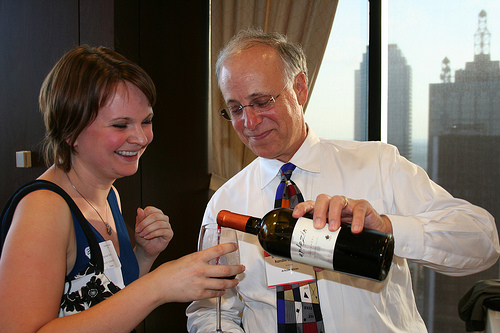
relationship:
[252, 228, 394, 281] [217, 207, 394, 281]
wine inside bottle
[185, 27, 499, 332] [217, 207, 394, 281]
man holding bottle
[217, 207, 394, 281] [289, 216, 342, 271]
bottle has label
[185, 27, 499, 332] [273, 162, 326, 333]
man wearing tie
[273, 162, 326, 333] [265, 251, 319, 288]
tie has nametag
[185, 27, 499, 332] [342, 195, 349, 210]
man wearing ring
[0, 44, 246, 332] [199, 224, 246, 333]
woman holding wineglass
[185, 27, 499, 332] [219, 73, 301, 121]
man wearing eyeglasses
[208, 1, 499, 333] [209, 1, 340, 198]
window has curtain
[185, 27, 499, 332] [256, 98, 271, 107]
man has eye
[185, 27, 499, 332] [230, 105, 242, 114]
man has eye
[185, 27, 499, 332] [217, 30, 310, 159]
man has head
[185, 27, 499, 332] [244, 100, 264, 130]
man has nose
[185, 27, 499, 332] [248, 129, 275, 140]
man has mouth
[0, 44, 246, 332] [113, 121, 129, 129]
woman has eye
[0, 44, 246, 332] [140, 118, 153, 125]
woman has eye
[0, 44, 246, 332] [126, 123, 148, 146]
woman has nose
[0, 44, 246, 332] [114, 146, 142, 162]
woman has mouth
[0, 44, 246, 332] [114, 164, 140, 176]
woman has chin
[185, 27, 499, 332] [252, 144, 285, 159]
man has chin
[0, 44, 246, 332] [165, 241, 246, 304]
woman has hand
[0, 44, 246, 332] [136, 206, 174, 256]
woman has hand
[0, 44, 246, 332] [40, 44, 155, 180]
woman has head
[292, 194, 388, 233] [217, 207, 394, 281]
hand holds bottle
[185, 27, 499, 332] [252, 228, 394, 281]
man pouring wine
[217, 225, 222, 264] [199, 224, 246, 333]
wine inside wineglass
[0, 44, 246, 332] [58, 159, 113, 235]
woman wearing necklace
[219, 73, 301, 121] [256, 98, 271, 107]
eyeglasses are in front of eye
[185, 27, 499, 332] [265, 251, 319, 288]
man wearing nametag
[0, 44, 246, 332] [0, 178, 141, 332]
woman wearing dress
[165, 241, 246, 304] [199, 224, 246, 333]
hand holding wineglass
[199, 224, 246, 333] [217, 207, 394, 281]
wineglass beneath bottle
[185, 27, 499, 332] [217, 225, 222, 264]
man pouring wine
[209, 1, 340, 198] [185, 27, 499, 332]
curtain behind man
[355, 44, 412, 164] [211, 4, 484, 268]
building seen outside window